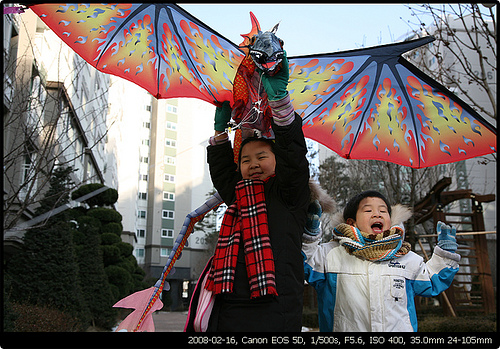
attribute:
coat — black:
[204, 112, 307, 328]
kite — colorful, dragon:
[20, 0, 497, 164]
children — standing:
[186, 117, 471, 335]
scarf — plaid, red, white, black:
[199, 175, 284, 301]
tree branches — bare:
[410, 10, 500, 100]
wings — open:
[126, 16, 412, 168]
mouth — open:
[374, 224, 384, 230]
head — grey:
[241, 25, 288, 70]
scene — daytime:
[38, 40, 480, 251]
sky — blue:
[303, 4, 396, 39]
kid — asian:
[320, 175, 416, 325]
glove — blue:
[434, 220, 462, 249]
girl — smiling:
[201, 122, 317, 334]